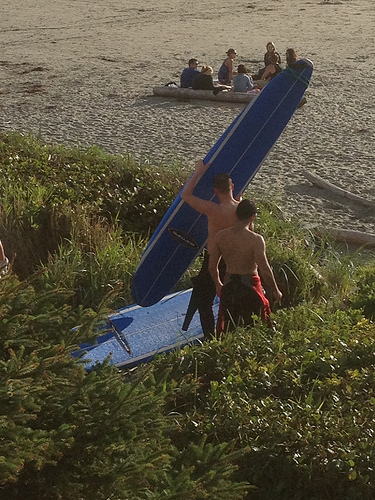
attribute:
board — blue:
[119, 50, 318, 310]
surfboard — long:
[131, 54, 311, 300]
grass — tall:
[3, 128, 371, 496]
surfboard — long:
[143, 77, 365, 386]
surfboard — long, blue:
[52, 55, 313, 322]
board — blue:
[129, 58, 314, 308]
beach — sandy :
[1, 0, 374, 238]